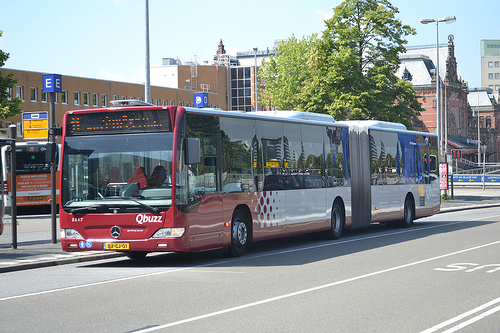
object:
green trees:
[251, 0, 420, 121]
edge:
[166, 105, 183, 253]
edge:
[174, 108, 348, 128]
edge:
[344, 123, 351, 228]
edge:
[366, 126, 372, 223]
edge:
[251, 225, 331, 242]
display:
[68, 110, 173, 135]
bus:
[56, 99, 440, 261]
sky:
[6, 5, 118, 55]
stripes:
[331, 258, 431, 287]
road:
[0, 197, 500, 333]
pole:
[436, 23, 440, 193]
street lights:
[439, 16, 457, 25]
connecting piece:
[350, 124, 369, 230]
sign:
[42, 74, 63, 93]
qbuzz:
[136, 214, 162, 225]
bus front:
[60, 107, 187, 252]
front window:
[60, 133, 172, 211]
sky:
[132, 50, 216, 62]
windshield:
[54, 130, 178, 216]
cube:
[43, 75, 62, 93]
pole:
[49, 91, 55, 244]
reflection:
[186, 117, 346, 189]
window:
[175, 134, 221, 206]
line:
[127, 292, 300, 332]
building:
[0, 65, 228, 121]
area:
[0, 178, 500, 333]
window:
[220, 134, 257, 192]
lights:
[419, 18, 435, 24]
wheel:
[319, 201, 346, 239]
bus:
[4, 139, 65, 215]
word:
[135, 214, 163, 225]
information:
[91, 119, 145, 124]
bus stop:
[16, 73, 120, 243]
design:
[253, 191, 286, 226]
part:
[290, 267, 330, 311]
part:
[340, 221, 347, 229]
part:
[383, 260, 421, 274]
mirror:
[186, 138, 200, 164]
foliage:
[268, 68, 306, 102]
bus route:
[69, 115, 165, 132]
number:
[71, 118, 80, 130]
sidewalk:
[0, 249, 90, 268]